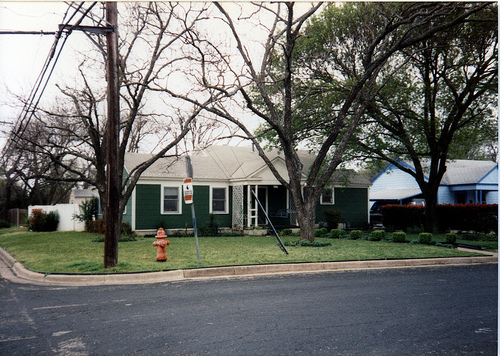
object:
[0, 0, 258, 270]
tree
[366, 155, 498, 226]
house